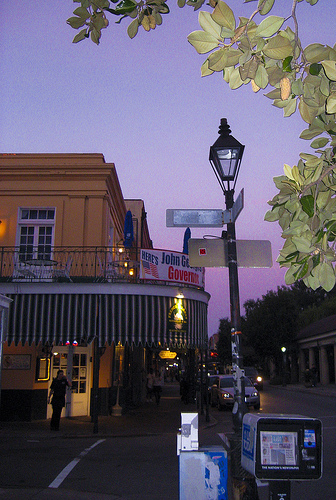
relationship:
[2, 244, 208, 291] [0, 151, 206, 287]
balcony on rooftop area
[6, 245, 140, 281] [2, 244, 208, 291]
patio set on top of balcony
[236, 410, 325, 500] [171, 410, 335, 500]
newspaper stand on a corner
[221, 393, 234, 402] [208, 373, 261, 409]
headlight on a car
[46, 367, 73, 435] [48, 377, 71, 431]
woman wearing black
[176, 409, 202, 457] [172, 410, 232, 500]
top of a newspaper stand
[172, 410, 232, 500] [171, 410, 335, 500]
newspaper stand on a corner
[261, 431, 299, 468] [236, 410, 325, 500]
newspaper inside newspaper stand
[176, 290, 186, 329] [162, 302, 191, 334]
light reflected over sign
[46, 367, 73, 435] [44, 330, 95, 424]
woman walking from doorway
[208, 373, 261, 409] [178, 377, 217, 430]
car parked at curb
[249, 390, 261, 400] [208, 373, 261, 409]
headlight of a car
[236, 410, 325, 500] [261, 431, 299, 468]
newspaper stand dispenses usa today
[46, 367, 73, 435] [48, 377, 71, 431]
woman wearing black clothes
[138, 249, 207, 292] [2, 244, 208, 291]
campaign sign hanging on a balcony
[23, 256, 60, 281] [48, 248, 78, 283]
table has chair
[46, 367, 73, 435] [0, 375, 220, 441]
woman walking on sidewalk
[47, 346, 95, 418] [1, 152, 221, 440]
door for restaurant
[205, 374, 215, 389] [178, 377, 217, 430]
car parked by curb